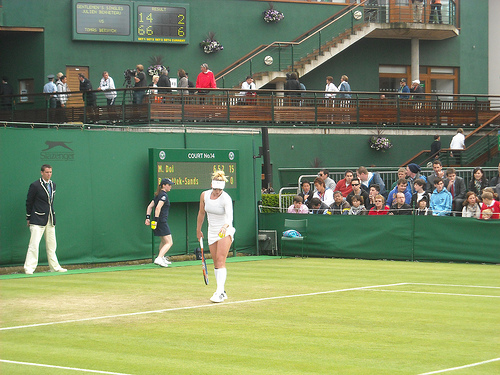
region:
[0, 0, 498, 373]
A tennis match is being played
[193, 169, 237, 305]
The woman is preparing to serve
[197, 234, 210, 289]
A tennis racket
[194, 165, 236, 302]
The woman is dressed in white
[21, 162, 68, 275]
This man is the back judge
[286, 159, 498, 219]
Spectators are watching the match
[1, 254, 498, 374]
The court surface is grass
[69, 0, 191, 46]
A scoreboard is on the wall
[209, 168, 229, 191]
The woman is wearing a sun visor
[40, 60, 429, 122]
People are standing on the walkway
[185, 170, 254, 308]
woman bouncing tennis ball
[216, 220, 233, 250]
yellow tennis ball in left hand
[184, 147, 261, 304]
woman playing tennis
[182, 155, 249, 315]
woman wearing white visor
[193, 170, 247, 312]
woman holding tennis racket with right hand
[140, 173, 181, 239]
woman wearing black out fit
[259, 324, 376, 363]
green tennis court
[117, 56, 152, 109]
man next to camera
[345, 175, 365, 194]
man wearing sun glasses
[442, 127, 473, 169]
person walking up stairs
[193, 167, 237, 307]
Athletic tennis player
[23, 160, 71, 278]
Tennis official watching game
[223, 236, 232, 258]
hand of tennis player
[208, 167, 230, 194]
Head of tennis player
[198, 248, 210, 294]
Racket of tennis player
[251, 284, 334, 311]
Part of white tennis court stripe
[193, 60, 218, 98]
Person watching tennis match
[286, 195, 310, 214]
Person watching tennis match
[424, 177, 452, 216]
Person watching tennis match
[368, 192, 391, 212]
Person watching tennis match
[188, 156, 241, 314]
tennis player wears white clothes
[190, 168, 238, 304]
tennis player is blonde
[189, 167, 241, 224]
tennis player wears a white headband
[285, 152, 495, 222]
viewers on side the tennis court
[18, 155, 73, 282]
man stand on back of tennis court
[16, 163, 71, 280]
man wears white pants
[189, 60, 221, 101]
man with red top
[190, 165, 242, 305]
tennis player holds a ball on left hand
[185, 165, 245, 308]
tennis player holds a racket on right hand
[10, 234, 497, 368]
tennis court is green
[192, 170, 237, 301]
female tennis player on a court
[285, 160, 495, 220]
small crowd of men and women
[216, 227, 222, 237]
tennis ball in the woman's hand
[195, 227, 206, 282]
tennis racket in a woman's hand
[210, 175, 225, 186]
white visor on a tennis player's head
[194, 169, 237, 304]
female tennis player dressed in all white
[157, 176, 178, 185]
dark colored hat on a woman's head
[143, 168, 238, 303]
two women on a tennis court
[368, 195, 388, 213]
woman in the crowd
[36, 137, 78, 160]
black logo design on a wall